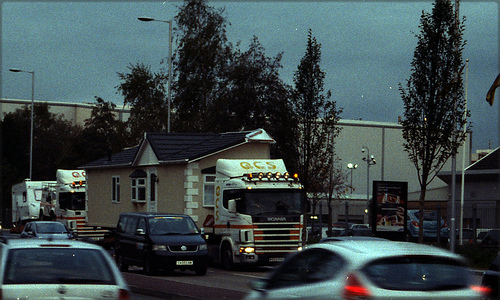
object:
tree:
[398, 0, 474, 237]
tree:
[211, 35, 297, 170]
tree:
[162, 3, 234, 151]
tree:
[116, 61, 169, 154]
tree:
[78, 91, 134, 151]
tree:
[1, 99, 87, 192]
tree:
[291, 21, 357, 224]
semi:
[199, 158, 308, 273]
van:
[112, 212, 208, 279]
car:
[398, 207, 451, 242]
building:
[433, 140, 498, 248]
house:
[80, 128, 276, 237]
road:
[0, 228, 499, 298]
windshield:
[246, 190, 302, 216]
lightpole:
[137, 17, 174, 134]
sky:
[0, 1, 499, 153]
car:
[242, 239, 487, 299]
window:
[364, 256, 466, 289]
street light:
[136, 17, 170, 30]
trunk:
[419, 158, 427, 244]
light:
[342, 271, 372, 300]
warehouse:
[0, 98, 470, 231]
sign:
[369, 180, 407, 239]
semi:
[51, 169, 109, 242]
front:
[241, 180, 301, 261]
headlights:
[239, 247, 258, 255]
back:
[348, 249, 483, 299]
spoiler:
[213, 158, 289, 181]